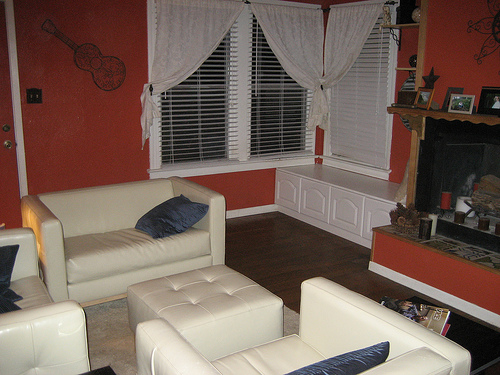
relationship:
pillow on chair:
[0, 243, 26, 303] [0, 226, 96, 373]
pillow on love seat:
[137, 188, 209, 242] [20, 177, 229, 305]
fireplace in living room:
[413, 116, 499, 250] [0, 2, 498, 373]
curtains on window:
[140, 1, 382, 166] [157, 4, 390, 171]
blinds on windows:
[159, 10, 393, 167] [157, 4, 390, 171]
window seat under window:
[268, 157, 413, 247] [157, 4, 390, 171]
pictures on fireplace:
[411, 84, 499, 112] [413, 116, 499, 250]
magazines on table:
[377, 296, 454, 336] [385, 290, 498, 374]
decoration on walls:
[42, 16, 126, 90] [0, 1, 495, 314]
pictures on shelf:
[411, 84, 499, 112] [384, 101, 499, 140]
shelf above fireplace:
[384, 101, 499, 140] [413, 116, 499, 250]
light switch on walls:
[25, 88, 46, 106] [0, 1, 495, 314]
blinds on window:
[159, 10, 393, 167] [157, 4, 390, 171]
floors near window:
[221, 208, 415, 309] [157, 4, 390, 171]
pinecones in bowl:
[389, 202, 423, 228] [392, 215, 424, 231]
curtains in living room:
[140, 1, 382, 166] [0, 2, 498, 373]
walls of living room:
[0, 1, 495, 314] [0, 2, 498, 373]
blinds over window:
[159, 10, 393, 167] [157, 4, 390, 171]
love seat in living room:
[20, 177, 229, 305] [0, 2, 498, 373]